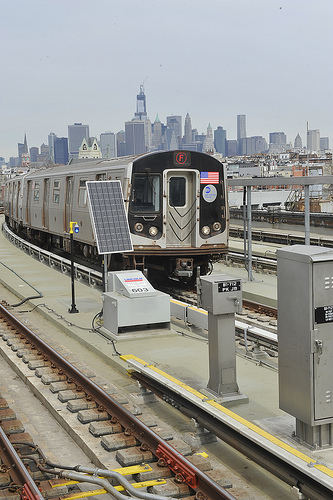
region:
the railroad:
[110, 427, 151, 458]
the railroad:
[129, 443, 167, 497]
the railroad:
[151, 423, 184, 491]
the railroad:
[143, 447, 172, 491]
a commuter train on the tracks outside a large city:
[7, 148, 237, 297]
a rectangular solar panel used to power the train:
[82, 180, 137, 299]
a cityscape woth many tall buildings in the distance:
[7, 75, 328, 159]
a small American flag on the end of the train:
[199, 171, 220, 186]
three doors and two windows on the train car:
[25, 177, 76, 235]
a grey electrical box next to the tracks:
[274, 237, 331, 446]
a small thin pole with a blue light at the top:
[67, 218, 82, 316]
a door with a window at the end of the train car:
[165, 172, 199, 254]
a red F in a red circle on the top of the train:
[171, 151, 189, 166]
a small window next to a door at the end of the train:
[127, 173, 158, 216]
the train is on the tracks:
[11, 138, 235, 282]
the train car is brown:
[26, 154, 246, 255]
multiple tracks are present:
[0, 276, 290, 498]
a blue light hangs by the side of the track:
[65, 215, 91, 255]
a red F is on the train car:
[173, 149, 192, 174]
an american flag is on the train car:
[197, 168, 230, 192]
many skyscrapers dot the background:
[38, 90, 292, 161]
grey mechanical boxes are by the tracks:
[182, 264, 250, 449]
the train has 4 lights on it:
[116, 200, 236, 244]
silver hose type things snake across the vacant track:
[44, 451, 193, 497]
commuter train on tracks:
[25, 138, 245, 288]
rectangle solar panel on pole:
[82, 170, 135, 270]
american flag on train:
[197, 167, 225, 188]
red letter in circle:
[171, 148, 192, 168]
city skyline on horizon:
[118, 104, 297, 161]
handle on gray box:
[307, 324, 328, 366]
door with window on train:
[160, 166, 200, 252]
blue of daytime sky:
[215, 72, 274, 100]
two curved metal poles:
[75, 457, 138, 497]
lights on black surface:
[148, 221, 214, 240]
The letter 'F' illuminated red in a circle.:
[174, 149, 188, 164]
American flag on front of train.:
[200, 170, 219, 184]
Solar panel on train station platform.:
[84, 180, 133, 253]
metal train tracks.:
[2, 316, 188, 486]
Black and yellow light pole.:
[69, 221, 80, 313]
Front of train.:
[124, 150, 229, 250]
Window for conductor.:
[133, 172, 160, 218]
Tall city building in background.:
[125, 80, 151, 151]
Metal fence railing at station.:
[236, 175, 324, 281]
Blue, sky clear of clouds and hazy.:
[23, 21, 292, 60]